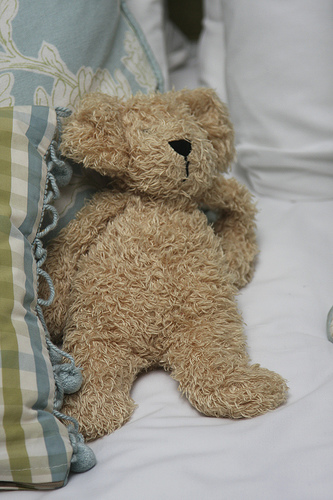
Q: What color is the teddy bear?
A: Tan.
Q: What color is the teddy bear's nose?
A: Black.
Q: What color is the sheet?
A: White.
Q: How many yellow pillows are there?
A: 0.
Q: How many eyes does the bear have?
A: 0.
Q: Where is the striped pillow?
A: On the left.